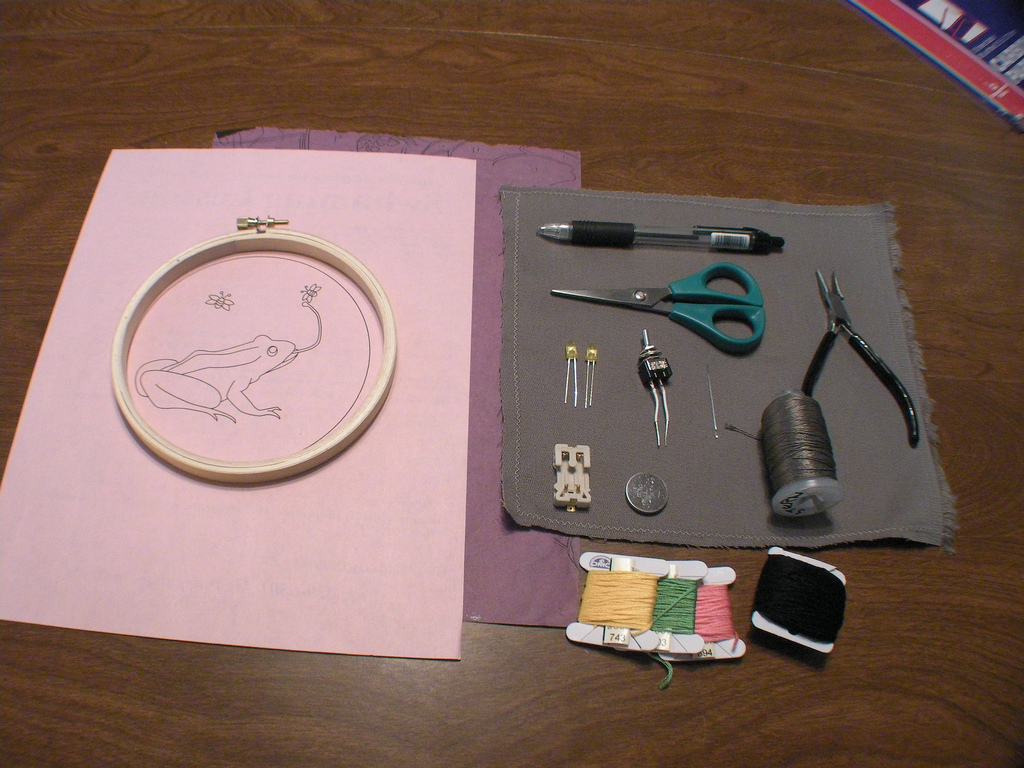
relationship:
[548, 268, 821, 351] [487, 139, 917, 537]
scissors on cloth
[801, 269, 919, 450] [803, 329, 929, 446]
pliers with handle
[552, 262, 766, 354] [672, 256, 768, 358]
scissors with handle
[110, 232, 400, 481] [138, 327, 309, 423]
ring over frog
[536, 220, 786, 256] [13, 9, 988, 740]
pen on table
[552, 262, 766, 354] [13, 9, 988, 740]
scissors on table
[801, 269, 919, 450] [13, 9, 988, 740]
pliers on table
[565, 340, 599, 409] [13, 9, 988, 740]
resistors on table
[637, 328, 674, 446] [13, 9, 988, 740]
switch on table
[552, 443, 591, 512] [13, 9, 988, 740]
tool on table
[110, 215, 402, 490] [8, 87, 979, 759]
tool on table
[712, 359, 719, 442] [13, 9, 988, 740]
tool on table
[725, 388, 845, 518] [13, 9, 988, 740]
tool on table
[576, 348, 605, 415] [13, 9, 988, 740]
tool on table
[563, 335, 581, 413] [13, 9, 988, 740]
tool on table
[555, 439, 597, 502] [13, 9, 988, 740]
tool on table